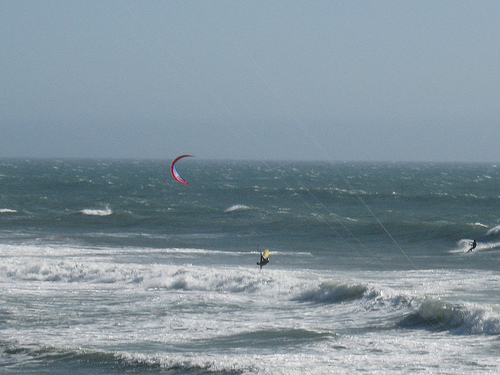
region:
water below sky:
[0, 159, 499, 373]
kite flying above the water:
[169, 153, 195, 184]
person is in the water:
[464, 239, 479, 253]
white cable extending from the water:
[207, 1, 417, 272]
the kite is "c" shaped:
[170, 154, 195, 185]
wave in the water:
[61, 208, 133, 224]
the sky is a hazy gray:
[1, 2, 499, 166]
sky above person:
[1, 0, 499, 159]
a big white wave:
[1, 256, 498, 335]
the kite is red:
[170, 152, 198, 184]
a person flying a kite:
[245, 242, 277, 270]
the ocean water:
[150, 297, 268, 338]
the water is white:
[126, 262, 197, 293]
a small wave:
[82, 204, 141, 224]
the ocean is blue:
[370, 158, 475, 210]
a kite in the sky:
[165, 147, 207, 193]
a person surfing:
[461, 235, 478, 257]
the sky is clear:
[57, 87, 140, 126]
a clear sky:
[29, 66, 144, 105]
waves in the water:
[96, 301, 119, 326]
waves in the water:
[238, 324, 264, 335]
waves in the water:
[285, 300, 312, 317]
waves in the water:
[242, 290, 289, 323]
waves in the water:
[103, 335, 124, 349]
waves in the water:
[380, 327, 405, 346]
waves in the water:
[372, 303, 401, 313]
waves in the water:
[336, 292, 352, 303]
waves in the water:
[153, 345, 176, 369]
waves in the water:
[133, 329, 148, 345]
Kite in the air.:
[137, 114, 272, 231]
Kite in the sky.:
[133, 119, 256, 242]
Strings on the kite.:
[264, 89, 470, 356]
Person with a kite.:
[132, 122, 344, 331]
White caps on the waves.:
[130, 239, 327, 355]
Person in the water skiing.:
[395, 204, 492, 264]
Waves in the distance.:
[68, 148, 144, 227]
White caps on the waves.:
[62, 157, 135, 231]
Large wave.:
[298, 242, 364, 332]